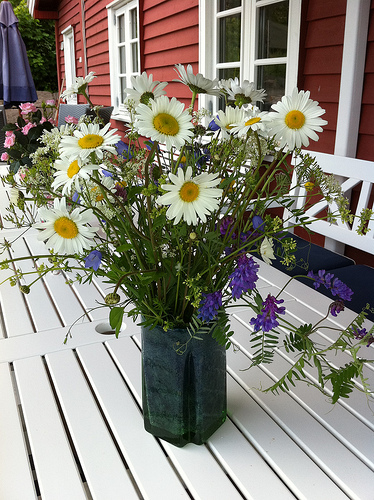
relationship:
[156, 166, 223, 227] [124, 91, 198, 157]
daisies next flower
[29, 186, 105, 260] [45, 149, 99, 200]
flower next flower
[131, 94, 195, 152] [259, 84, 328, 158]
flowers next flower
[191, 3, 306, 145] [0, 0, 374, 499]
window in house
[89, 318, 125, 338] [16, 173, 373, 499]
hole on table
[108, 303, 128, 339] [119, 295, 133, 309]
leaf on stem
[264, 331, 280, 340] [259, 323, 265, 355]
leaf on stem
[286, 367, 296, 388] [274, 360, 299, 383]
leaf on stem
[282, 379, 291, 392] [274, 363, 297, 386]
leaf on stem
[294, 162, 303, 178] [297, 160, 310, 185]
leaf on stem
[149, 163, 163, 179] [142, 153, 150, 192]
leaf on stem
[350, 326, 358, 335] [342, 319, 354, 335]
leaf on stem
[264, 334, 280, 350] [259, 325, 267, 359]
leaf on stem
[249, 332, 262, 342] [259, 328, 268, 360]
leaf on stem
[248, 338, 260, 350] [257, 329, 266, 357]
leaf on stem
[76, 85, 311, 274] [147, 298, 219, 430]
daisies are inside of vase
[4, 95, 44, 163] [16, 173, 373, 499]
flowers are on top of table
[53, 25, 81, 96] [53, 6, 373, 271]
door attached to house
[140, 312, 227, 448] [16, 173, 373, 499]
vase on top of table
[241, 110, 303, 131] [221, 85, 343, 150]
centers are growing in flowers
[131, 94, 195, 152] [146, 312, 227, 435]
flowers are inside of vase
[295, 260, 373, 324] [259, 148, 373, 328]
cushion are on top of bench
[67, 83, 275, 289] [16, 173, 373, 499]
flowers are on top of table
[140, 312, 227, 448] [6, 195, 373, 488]
vase on top of table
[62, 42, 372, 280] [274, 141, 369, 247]
house behind bench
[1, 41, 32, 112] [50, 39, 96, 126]
umbrella in front of window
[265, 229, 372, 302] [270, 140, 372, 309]
cushion on top of bench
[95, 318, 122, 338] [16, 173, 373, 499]
hole inside of table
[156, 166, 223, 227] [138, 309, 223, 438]
daisies inside of vase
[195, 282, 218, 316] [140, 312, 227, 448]
flower inside of vase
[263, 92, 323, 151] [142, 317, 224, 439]
flower inside of vase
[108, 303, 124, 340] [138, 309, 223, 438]
leaf inside of vase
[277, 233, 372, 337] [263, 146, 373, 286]
cushion on top of bench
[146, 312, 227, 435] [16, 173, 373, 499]
vase on top of table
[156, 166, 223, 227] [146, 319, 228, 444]
daisies inside of vase